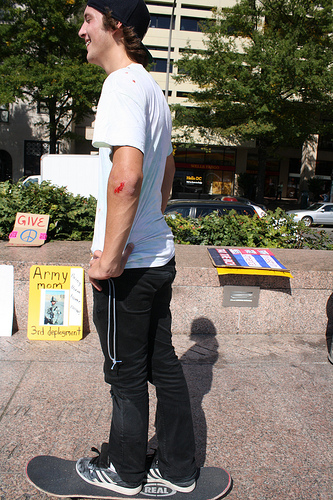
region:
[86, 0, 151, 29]
A hat worn on some guys head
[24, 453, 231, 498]
A skateboard riding along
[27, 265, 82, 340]
A sign with a person on it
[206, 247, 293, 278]
A couple of signs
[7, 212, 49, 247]
A give peace sign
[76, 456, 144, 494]
An Adidas athletic shoe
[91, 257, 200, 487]
Black pants worn by a guy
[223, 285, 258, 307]
A vent on the side of a walkway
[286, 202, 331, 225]
A silver motor vehicle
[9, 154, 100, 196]
A box truck driving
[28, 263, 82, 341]
yellow sign that says Army Mom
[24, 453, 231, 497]
black skateboard with white lettering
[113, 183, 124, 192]
blood on the guy's arm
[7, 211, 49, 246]
cardboard sign with peace sign on it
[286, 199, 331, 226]
grey car parked at the curb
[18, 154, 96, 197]
large white work truck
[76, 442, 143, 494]
black tennis shoe with white stripes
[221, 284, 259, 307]
silver metal plate on the step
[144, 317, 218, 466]
person's shadow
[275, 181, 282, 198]
person standing in the background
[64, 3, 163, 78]
the heamand of a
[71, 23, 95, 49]
the nose of a man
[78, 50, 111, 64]
the chin of a man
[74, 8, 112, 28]
the eye of a man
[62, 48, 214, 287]
a man wearing a shirt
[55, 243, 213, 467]
a man wearing jeans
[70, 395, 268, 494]
a man wearing shoes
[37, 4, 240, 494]
a man on a skateboard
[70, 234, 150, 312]
the hand of a man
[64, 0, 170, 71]
a man with a hat on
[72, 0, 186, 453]
this is a man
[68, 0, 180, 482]
the man is standing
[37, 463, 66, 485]
this is a skate board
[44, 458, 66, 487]
the board is black in color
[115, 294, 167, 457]
the trousers are black in color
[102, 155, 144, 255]
this is the hand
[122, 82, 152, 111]
the t shirt is white in color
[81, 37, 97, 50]
the man is smiling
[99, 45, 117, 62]
the man is light skinned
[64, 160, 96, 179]
the lorry is parked